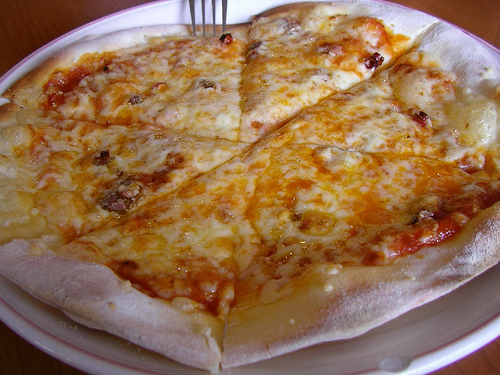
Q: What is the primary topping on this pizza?
A: Cheese.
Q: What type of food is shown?
A: Pizza.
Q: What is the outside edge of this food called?
A: Crust.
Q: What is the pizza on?
A: White plate.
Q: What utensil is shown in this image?
A: Fork.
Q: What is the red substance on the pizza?
A: Sauce.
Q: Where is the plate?
A: Under the pizza.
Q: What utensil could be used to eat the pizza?
A: Fork.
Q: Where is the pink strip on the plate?
A: Border.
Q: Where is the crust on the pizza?
A: Outside edge.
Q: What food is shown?
A: Pizza.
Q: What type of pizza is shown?
A: Cheese.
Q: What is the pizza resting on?
A: A plate.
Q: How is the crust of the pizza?
A: Thin.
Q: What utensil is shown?
A: Fork.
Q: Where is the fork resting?
A: Plate edge.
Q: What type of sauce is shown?
A: Tomato.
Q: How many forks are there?
A: One.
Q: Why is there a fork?
A: To eat the food.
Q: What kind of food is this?
A: Pizza.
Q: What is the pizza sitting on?
A: A plate.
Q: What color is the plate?
A: White.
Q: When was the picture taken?
A: Daytime.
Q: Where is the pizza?
A: On the plate.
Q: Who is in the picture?
A: Nobody.